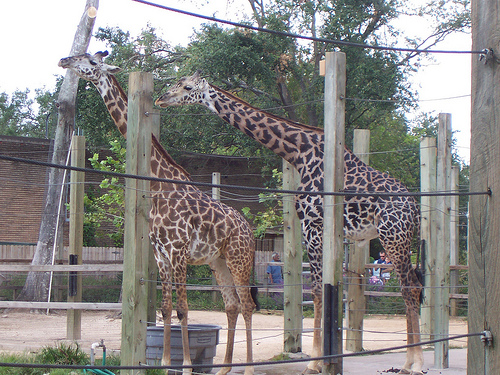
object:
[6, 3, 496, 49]
sky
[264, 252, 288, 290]
man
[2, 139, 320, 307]
building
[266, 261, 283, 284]
shirt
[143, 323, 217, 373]
trash can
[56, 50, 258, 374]
giraffe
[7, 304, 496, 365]
ground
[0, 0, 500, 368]
zoo pen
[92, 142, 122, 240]
tree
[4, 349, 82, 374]
grass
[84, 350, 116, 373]
garden hose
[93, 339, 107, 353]
faucet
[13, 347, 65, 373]
bushes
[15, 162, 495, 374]
fence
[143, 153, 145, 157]
hole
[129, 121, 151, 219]
wood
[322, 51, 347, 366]
post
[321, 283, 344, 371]
bottom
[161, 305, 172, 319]
knees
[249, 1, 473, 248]
tree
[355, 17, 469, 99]
branch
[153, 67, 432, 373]
giraffe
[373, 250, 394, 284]
man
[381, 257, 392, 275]
child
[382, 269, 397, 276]
arms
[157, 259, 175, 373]
front legs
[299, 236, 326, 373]
front legs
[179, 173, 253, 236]
back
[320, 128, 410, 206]
back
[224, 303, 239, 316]
knees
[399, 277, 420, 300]
knees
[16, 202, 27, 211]
brick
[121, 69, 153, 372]
pole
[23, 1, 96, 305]
tree trunk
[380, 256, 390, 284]
people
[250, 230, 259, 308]
tail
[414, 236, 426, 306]
tail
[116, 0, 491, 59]
rods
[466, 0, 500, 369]
post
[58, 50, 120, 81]
giraffe head